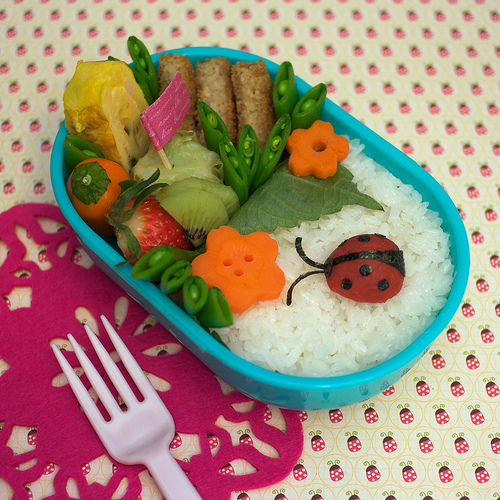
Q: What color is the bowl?
A: Blue.